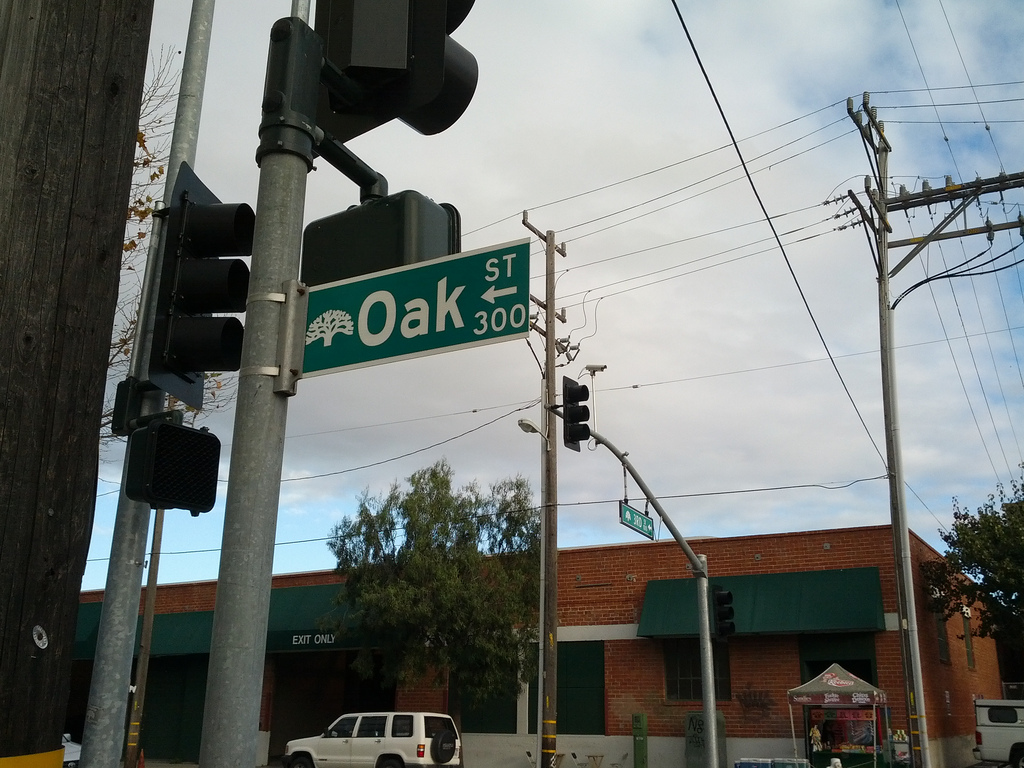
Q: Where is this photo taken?
A: Outside on Oak st.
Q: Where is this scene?
A: On Oak St.